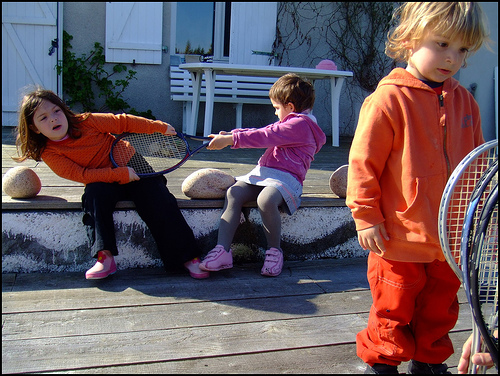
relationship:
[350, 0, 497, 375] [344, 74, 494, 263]
boy wearing jacket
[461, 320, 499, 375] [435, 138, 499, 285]
hand holding tennis racket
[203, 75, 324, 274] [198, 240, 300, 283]
girl has boots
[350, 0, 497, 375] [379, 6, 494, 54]
boy has hair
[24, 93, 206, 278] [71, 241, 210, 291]
girl has sports shoes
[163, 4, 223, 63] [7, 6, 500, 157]
window in background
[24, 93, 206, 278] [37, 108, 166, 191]
girl wearing shirt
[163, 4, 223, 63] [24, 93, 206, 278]
window behind girl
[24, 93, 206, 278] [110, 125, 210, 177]
girl pulling tennis racket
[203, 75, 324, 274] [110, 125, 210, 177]
girl holding tennis racket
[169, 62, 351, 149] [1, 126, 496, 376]
table on walkway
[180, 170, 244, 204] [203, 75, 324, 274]
stone next to girl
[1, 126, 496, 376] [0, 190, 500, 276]
walkway has step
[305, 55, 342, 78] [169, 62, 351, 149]
tap light on table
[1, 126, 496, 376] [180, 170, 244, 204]
walkway has stone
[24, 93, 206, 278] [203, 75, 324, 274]
girl fighting girl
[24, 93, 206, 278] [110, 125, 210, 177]
girl fighting over tennis racket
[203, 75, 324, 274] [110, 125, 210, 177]
girl fighting over tennis racket